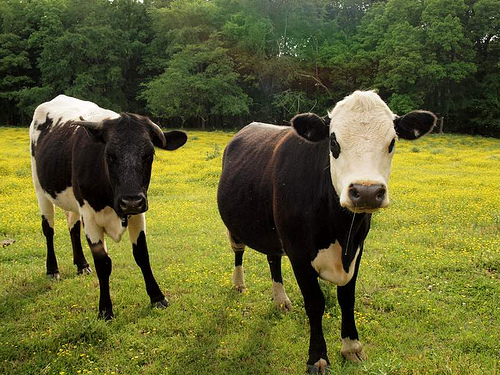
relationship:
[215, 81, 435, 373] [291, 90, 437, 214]
cow has head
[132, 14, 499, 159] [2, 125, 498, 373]
trees next to field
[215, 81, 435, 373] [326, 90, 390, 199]
cow has face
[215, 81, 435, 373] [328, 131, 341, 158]
cow has an eye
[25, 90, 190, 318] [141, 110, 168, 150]
cow has horn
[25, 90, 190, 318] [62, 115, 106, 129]
cow has horn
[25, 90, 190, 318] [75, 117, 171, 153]
cow has horns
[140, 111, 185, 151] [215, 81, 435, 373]
horn on cow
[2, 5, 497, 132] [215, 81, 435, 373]
area behind cow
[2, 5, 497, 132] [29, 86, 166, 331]
area behind cow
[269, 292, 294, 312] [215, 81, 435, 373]
white hoof on cow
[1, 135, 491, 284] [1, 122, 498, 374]
flowers are on grass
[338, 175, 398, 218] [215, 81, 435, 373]
nose has cow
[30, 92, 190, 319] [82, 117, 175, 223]
cow has head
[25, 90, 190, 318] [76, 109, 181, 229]
cow has head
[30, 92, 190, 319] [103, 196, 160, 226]
cow has muzzle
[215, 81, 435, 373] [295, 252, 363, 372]
cow has legs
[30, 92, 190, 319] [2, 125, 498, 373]
cow standing in a field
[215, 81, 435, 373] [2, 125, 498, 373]
cow standing in a field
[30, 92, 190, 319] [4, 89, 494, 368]
cow standing in a field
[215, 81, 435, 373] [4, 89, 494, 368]
cow standing in a field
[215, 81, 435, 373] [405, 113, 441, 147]
cow has ear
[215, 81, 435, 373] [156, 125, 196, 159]
cow has ear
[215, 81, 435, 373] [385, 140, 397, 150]
cow has eye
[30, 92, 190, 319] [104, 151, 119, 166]
cow has eye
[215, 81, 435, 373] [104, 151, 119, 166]
cow has eye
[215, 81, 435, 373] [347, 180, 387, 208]
cow has nose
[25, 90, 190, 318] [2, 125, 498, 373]
cow standing on field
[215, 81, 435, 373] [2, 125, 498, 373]
cow standing on field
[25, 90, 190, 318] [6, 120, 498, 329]
cow on field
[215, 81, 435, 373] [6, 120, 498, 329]
cow on field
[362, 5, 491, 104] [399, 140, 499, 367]
tree on field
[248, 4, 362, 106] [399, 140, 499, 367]
tree on field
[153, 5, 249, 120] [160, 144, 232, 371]
tree on field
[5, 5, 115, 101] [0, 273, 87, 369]
tree on field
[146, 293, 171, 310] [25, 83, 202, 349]
hoof on cow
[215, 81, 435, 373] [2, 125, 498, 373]
cow on field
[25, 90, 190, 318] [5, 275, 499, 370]
cow in field